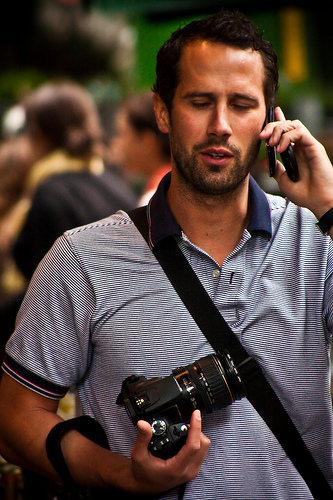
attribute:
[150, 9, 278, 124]
hair — black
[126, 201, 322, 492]
strap — black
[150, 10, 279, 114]
hair — dark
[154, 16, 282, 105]
hair — short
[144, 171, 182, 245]
collar — blue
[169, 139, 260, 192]
facial hair — dark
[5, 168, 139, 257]
shirt — black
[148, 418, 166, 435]
camera dial — black, white, green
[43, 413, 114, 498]
camera strap — black